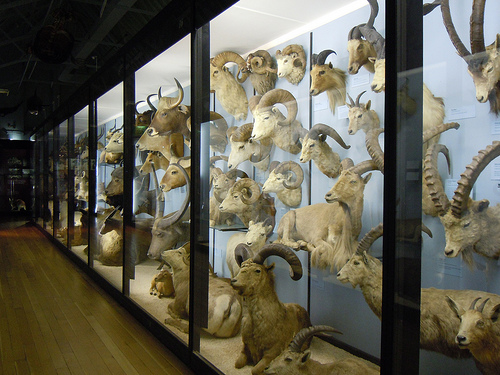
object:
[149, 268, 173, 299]
baby lamb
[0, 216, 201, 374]
mat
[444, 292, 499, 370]
goat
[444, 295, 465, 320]
ear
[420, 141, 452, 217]
horn bumps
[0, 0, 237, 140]
ceiling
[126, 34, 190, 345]
glass case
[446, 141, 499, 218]
horn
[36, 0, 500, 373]
stuffed animals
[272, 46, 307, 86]
animal heads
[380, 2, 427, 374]
pillar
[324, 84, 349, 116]
hair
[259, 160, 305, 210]
animal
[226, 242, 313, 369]
animal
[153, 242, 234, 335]
animal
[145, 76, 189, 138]
bull's head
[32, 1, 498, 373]
case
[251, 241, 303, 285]
horn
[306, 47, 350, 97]
head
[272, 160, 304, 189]
horns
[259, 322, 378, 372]
ram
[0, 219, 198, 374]
floor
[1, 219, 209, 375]
flooring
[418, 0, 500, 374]
glass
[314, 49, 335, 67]
curved horn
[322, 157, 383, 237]
sheep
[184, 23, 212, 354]
frame